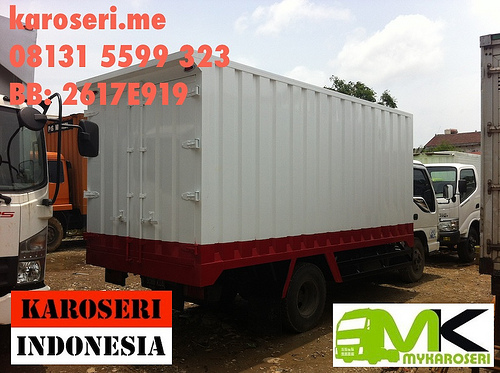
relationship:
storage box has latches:
[78, 51, 414, 244] [177, 82, 201, 211]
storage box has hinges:
[78, 51, 414, 244] [83, 108, 106, 121]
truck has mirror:
[412, 158, 440, 256] [429, 184, 454, 206]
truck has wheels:
[412, 158, 440, 256] [403, 238, 428, 281]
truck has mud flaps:
[412, 158, 440, 256] [99, 266, 197, 300]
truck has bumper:
[412, 158, 440, 256] [428, 238, 444, 254]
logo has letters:
[9, 289, 172, 366] [22, 297, 161, 321]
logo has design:
[332, 303, 494, 367] [335, 309, 385, 363]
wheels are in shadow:
[403, 238, 428, 281] [386, 277, 423, 293]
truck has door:
[412, 158, 440, 256] [414, 164, 434, 237]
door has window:
[414, 164, 434, 237] [413, 166, 436, 211]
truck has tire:
[412, 158, 440, 256] [281, 265, 328, 328]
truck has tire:
[412, 158, 440, 256] [403, 238, 428, 281]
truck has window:
[412, 158, 440, 256] [413, 166, 436, 211]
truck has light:
[412, 158, 440, 256] [439, 220, 460, 232]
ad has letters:
[7, 4, 232, 111] [7, 5, 165, 31]